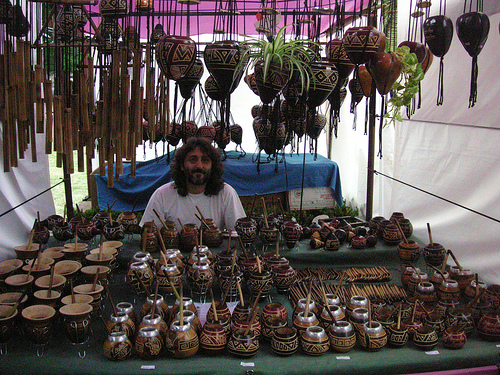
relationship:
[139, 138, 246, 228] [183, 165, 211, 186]
man has a beard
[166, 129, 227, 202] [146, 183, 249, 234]
old guy with a shirt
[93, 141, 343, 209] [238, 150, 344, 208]
tarp on a table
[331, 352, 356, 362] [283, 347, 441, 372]
sticker on tables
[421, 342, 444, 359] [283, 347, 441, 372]
sticker on tables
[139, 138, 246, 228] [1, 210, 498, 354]
man surrounded by pottery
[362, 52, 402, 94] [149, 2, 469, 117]
red pot hanging in macrame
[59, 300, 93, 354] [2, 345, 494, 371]
goblet on table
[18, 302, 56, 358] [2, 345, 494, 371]
goblet on table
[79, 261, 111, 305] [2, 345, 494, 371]
goblet on table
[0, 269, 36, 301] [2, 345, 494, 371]
goblet on table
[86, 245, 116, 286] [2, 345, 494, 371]
goblet on table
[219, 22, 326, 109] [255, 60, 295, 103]
plant hanging from pot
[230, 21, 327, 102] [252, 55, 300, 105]
fern in pot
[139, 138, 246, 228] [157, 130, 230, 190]
man has curly hair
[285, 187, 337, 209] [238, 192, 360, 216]
box on grass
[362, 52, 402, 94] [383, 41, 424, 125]
red pot has plant